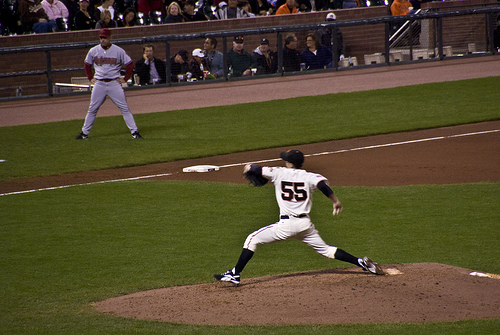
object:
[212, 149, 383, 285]
pitcher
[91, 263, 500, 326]
mound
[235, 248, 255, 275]
sock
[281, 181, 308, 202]
jersey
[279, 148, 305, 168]
hat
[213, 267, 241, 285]
cleat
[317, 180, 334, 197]
sleeve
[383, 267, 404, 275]
rubber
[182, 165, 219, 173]
base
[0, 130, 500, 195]
line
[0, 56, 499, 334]
field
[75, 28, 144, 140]
coach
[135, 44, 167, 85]
spectator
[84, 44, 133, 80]
shirt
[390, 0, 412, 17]
top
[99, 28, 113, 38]
cap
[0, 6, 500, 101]
fence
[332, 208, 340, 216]
ball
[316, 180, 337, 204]
arm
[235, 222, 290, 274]
leg